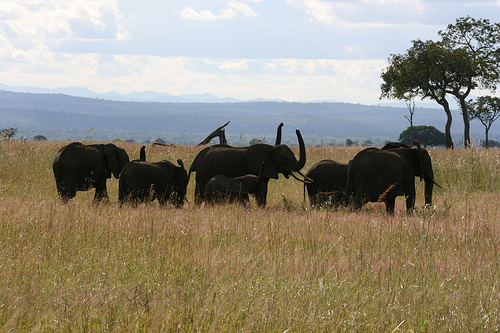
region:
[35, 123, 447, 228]
a herd of elephants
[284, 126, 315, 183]
trunk is lifted up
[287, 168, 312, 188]
two white tusks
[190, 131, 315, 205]
baby elephant standing by an adult elephant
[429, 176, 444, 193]
tusk on the side of the trunk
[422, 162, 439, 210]
trunk hanging down to the ground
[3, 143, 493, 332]
long, yellow grass on the ground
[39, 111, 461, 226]
elephants standing in the grass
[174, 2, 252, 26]
white cloud in the sky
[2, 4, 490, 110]
bright blue sky with several white clouds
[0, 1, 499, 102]
white clouds in blue sky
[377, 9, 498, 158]
three dark green trees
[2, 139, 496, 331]
not so green grassy plains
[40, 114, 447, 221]
dark colored elephants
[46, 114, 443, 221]
seven animals together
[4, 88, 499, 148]
land far off in the distance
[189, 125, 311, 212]
dark elephant with tusks holding his trunk up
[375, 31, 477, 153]
Tree with leaves on top and scraggy trunk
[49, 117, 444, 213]
animals together in the field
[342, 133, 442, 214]
an elephant showing us his backside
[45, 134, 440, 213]
these are elephants in the photo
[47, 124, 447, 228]
the elephants are in one place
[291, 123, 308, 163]
this is the trunk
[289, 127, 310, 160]
the trunk is raised up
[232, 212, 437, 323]
the grass are tall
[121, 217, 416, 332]
the grass are brown in color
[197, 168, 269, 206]
this is a calf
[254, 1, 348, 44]
the clouds are white in color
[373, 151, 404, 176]
this is the belly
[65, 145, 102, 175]
the elephant is black in color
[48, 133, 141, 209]
gray elephant on plain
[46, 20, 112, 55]
white clouds in blue sky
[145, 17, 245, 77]
white clouds in blue sky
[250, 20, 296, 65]
white clouds in blue sky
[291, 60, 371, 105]
white clouds in blue sky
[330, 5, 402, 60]
white clouds in blue sky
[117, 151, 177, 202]
gray elephant on plain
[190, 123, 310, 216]
gray elephant on plain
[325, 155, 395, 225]
gray elephant on plain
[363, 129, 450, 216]
gray elephant on plain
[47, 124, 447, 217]
group of elephants in a field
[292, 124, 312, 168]
raised trunk of an elephant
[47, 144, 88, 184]
butt of the elephant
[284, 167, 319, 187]
horns on an elephant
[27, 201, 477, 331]
a field of grass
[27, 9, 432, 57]
white clouds in the sky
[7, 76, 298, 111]
view of mountain range far ahead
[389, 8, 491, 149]
group of trees behind the elephants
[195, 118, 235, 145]
a broken tree bent 90 degrees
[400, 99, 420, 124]
a tree with no leaves